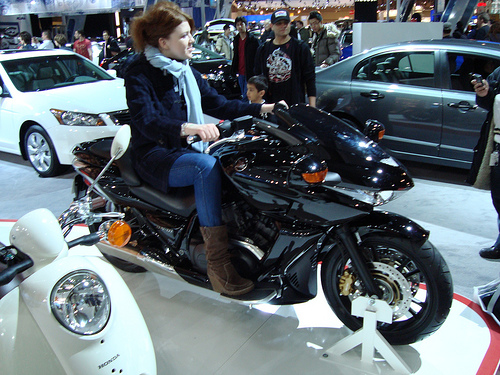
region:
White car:
[0, 47, 124, 176]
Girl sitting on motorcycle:
[126, 4, 290, 295]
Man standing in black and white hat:
[253, 8, 316, 109]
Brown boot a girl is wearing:
[196, 223, 258, 295]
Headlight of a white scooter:
[49, 270, 110, 336]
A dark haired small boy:
[243, 74, 270, 111]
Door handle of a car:
[358, 88, 384, 99]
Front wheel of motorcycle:
[321, 215, 455, 346]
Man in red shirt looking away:
[70, 29, 92, 60]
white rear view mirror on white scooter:
[108, 125, 135, 162]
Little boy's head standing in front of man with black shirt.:
[239, 73, 278, 100]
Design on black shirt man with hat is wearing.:
[261, 48, 301, 90]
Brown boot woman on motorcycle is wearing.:
[196, 217, 258, 304]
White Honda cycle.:
[0, 127, 154, 373]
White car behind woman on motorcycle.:
[1, 45, 122, 164]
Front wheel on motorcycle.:
[341, 213, 446, 358]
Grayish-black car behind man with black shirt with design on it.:
[333, 40, 498, 165]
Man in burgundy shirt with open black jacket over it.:
[223, 13, 247, 97]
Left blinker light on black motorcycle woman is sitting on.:
[290, 155, 332, 186]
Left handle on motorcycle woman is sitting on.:
[177, 116, 273, 146]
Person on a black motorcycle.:
[67, 2, 456, 344]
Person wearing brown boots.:
[111, 7, 258, 294]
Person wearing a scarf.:
[121, 3, 296, 300]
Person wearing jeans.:
[113, 1, 255, 298]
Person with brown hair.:
[121, 0, 302, 297]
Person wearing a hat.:
[249, 11, 319, 113]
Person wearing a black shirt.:
[255, 8, 323, 115]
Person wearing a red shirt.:
[68, 25, 94, 62]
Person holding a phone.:
[465, 56, 499, 264]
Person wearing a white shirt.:
[39, 29, 55, 51]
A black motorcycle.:
[101, 87, 448, 338]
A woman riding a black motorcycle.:
[75, 27, 437, 294]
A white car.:
[3, 47, 155, 164]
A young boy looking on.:
[235, 63, 292, 115]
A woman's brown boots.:
[171, 199, 273, 312]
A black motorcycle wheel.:
[309, 207, 445, 347]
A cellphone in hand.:
[450, 53, 495, 114]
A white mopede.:
[3, 120, 130, 370]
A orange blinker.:
[99, 209, 148, 256]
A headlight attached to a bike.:
[33, 253, 148, 349]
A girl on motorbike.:
[69, 9, 461, 349]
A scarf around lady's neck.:
[141, 45, 221, 153]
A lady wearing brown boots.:
[196, 222, 257, 303]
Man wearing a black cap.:
[266, 6, 298, 29]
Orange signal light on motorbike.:
[285, 148, 344, 200]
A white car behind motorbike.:
[1, 53, 128, 173]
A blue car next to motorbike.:
[314, 36, 498, 172]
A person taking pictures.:
[462, 62, 499, 108]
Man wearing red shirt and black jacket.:
[225, 33, 257, 79]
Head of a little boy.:
[242, 73, 273, 101]